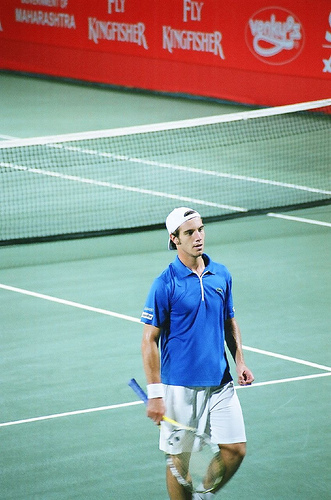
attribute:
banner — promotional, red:
[2, 0, 330, 118]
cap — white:
[164, 203, 201, 254]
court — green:
[1, 69, 328, 498]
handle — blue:
[126, 375, 180, 434]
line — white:
[2, 276, 331, 380]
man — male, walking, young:
[141, 204, 258, 500]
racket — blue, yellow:
[120, 367, 228, 495]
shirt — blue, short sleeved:
[138, 252, 238, 394]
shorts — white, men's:
[157, 379, 250, 459]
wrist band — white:
[144, 379, 169, 402]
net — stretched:
[1, 91, 328, 254]